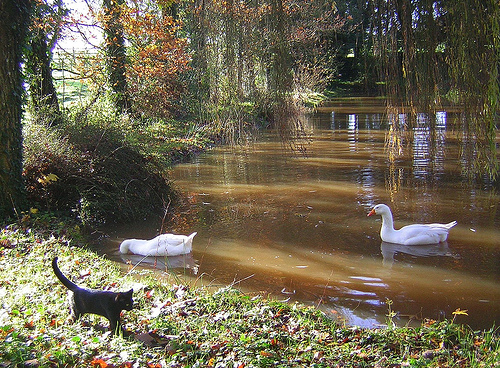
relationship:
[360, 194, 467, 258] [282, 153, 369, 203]
duck on water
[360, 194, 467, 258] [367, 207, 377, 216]
duck has beak